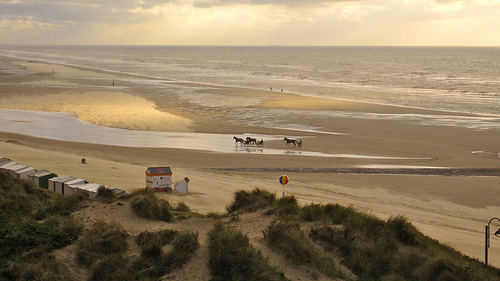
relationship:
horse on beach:
[284, 138, 299, 148] [0, 61, 498, 268]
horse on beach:
[247, 137, 259, 145] [0, 61, 498, 268]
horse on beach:
[233, 135, 244, 145] [0, 61, 498, 268]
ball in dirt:
[279, 176, 290, 186] [231, 153, 345, 190]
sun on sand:
[18, 91, 172, 130] [2, 139, 233, 213]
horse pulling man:
[247, 137, 259, 145] [257, 139, 264, 147]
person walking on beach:
[269, 85, 274, 93] [0, 61, 498, 268]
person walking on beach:
[279, 87, 284, 93] [0, 61, 498, 268]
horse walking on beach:
[284, 138, 299, 148] [0, 61, 498, 268]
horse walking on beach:
[247, 137, 259, 145] [0, 61, 498, 268]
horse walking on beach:
[233, 135, 244, 145] [0, 61, 498, 268]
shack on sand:
[145, 166, 172, 192] [2, 139, 233, 213]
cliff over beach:
[4, 178, 499, 280] [0, 61, 498, 268]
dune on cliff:
[230, 209, 270, 238] [53, 196, 461, 280]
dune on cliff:
[82, 205, 130, 224] [53, 196, 461, 280]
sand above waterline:
[0, 61, 498, 268] [8, 56, 496, 122]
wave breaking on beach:
[270, 62, 302, 71] [0, 61, 498, 268]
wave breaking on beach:
[430, 70, 481, 86] [0, 61, 498, 268]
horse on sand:
[284, 138, 299, 148] [2, 139, 233, 213]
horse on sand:
[284, 138, 299, 148] [0, 61, 498, 268]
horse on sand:
[233, 135, 244, 145] [2, 139, 233, 213]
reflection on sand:
[234, 147, 304, 157] [213, 144, 285, 160]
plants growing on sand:
[4, 178, 499, 280] [495, 280, 498, 281]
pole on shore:
[482, 225, 492, 267] [0, 61, 498, 268]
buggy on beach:
[296, 138, 303, 148] [0, 61, 498, 268]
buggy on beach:
[257, 139, 264, 147] [0, 61, 498, 268]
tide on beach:
[0, 42, 499, 114] [0, 61, 498, 268]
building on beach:
[145, 166, 172, 192] [0, 61, 498, 268]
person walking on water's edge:
[269, 85, 274, 93] [0, 42, 499, 114]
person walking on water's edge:
[279, 87, 284, 93] [0, 42, 499, 114]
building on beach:
[72, 182, 111, 202] [0, 61, 498, 268]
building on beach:
[47, 175, 92, 199] [0, 61, 498, 268]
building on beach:
[30, 168, 57, 190] [0, 61, 498, 268]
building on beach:
[0, 158, 41, 183] [0, 61, 498, 268]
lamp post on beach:
[484, 224, 490, 266] [0, 61, 498, 268]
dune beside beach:
[230, 209, 270, 238] [0, 61, 498, 268]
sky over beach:
[0, 0, 498, 47] [0, 61, 498, 268]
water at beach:
[0, 42, 499, 114] [0, 61, 498, 268]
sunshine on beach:
[18, 91, 172, 130] [0, 61, 498, 268]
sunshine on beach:
[251, 92, 369, 118] [0, 61, 498, 268]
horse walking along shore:
[284, 138, 299, 148] [0, 61, 498, 268]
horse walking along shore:
[247, 137, 259, 145] [0, 61, 498, 268]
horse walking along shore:
[233, 135, 244, 145] [0, 61, 498, 268]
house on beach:
[145, 166, 172, 192] [0, 61, 498, 268]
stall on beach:
[47, 175, 92, 199] [0, 61, 498, 268]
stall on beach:
[0, 158, 41, 183] [0, 61, 498, 268]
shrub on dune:
[273, 195, 299, 215] [230, 209, 270, 238]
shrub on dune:
[231, 189, 275, 208] [230, 209, 270, 238]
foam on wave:
[430, 72, 497, 84] [430, 70, 481, 86]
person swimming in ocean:
[269, 85, 274, 93] [0, 42, 499, 114]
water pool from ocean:
[2, 103, 432, 163] [10, 42, 497, 121]